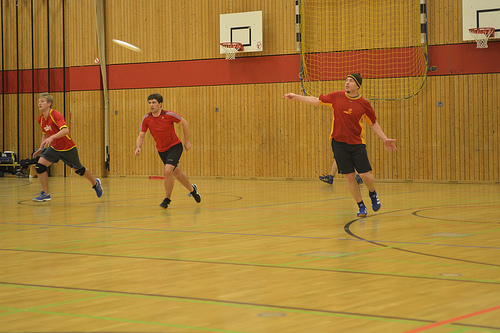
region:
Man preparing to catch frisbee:
[269, 58, 423, 223]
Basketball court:
[5, 178, 499, 323]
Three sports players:
[12, 85, 420, 227]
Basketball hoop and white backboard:
[212, 15, 273, 65]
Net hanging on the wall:
[273, 0, 431, 112]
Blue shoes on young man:
[347, 189, 402, 224]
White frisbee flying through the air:
[93, 25, 164, 63]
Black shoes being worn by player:
[140, 190, 185, 218]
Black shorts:
[149, 148, 190, 169]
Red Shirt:
[139, 113, 194, 153]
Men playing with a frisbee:
[12, 35, 403, 222]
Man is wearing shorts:
[327, 136, 377, 178]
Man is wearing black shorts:
[323, 133, 375, 176]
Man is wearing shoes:
[352, 192, 384, 222]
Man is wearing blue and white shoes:
[354, 192, 385, 219]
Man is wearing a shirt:
[315, 90, 383, 147]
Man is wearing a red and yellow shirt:
[315, 86, 381, 148]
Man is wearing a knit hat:
[345, 70, 366, 88]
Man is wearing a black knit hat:
[344, 70, 365, 87]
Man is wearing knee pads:
[32, 160, 88, 178]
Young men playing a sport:
[24, 71, 404, 225]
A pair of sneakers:
[31, 175, 105, 204]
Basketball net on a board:
[210, 7, 268, 61]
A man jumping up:
[282, 69, 400, 222]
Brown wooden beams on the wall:
[1, 2, 499, 185]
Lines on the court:
[1, 178, 498, 331]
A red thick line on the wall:
[2, 37, 497, 94]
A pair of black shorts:
[331, 134, 373, 176]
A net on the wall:
[291, 3, 435, 105]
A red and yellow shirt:
[314, 89, 379, 149]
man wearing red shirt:
[286, 41, 401, 216]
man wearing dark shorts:
[281, 68, 402, 223]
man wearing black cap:
[284, 69, 402, 217]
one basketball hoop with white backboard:
[206, 8, 267, 61]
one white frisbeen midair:
[109, 33, 143, 61]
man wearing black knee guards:
[18, 89, 108, 207]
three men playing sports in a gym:
[9, 57, 490, 323]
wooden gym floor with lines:
[12, 211, 489, 326]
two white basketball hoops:
[204, 6, 497, 59]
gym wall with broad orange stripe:
[11, 12, 493, 181]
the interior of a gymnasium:
[0, 0, 498, 332]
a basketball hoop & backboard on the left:
[218, 10, 263, 59]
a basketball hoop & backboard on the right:
[461, 0, 498, 48]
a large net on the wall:
[294, 0, 429, 102]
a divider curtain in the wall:
[92, 0, 109, 172]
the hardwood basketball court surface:
[0, 176, 499, 331]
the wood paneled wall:
[0, 0, 499, 185]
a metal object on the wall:
[437, 100, 442, 106]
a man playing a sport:
[135, 93, 201, 208]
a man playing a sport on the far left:
[32, 91, 103, 201]